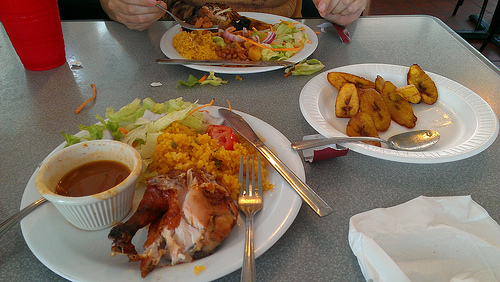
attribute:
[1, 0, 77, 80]
cup — red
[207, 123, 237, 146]
tomato — red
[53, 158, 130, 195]
gravy — brown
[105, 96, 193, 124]
lettuce — green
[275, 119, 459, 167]
spoon — silver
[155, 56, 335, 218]
knives — silver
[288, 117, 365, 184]
paper — white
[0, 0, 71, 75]
red cup — plastic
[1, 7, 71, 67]
cup — red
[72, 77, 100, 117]
carrot — long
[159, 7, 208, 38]
fork — silver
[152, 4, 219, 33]
fork — silver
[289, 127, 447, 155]
spoon — silver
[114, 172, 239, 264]
chicken — piece, barbecue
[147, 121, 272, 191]
rice — yellow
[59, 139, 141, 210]
sauce — brown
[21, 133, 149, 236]
cup — white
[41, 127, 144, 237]
bowl — white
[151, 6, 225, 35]
fork — silver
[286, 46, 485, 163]
plate — white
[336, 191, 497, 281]
paper — white